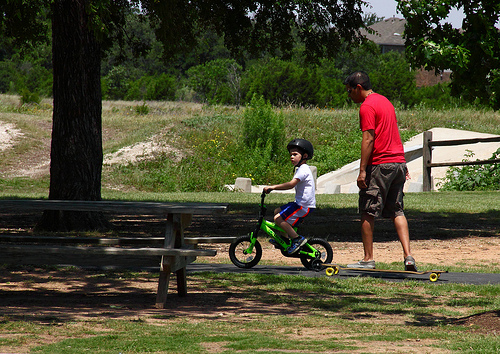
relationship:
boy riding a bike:
[261, 136, 311, 256] [220, 174, 341, 276]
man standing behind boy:
[344, 70, 416, 273] [261, 137, 323, 256]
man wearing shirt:
[344, 70, 416, 273] [346, 88, 431, 166]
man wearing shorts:
[344, 70, 416, 273] [358, 162, 407, 220]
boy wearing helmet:
[261, 136, 318, 252] [284, 137, 319, 157]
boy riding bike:
[261, 136, 318, 252] [230, 181, 335, 275]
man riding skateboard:
[344, 70, 416, 273] [332, 259, 455, 280]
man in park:
[344, 70, 416, 273] [2, 91, 499, 352]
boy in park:
[261, 136, 318, 252] [2, 91, 499, 352]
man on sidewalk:
[344, 70, 416, 273] [99, 258, 499, 286]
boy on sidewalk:
[261, 136, 318, 252] [99, 258, 499, 286]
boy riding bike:
[261, 136, 318, 252] [230, 186, 332, 268]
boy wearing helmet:
[261, 136, 318, 252] [269, 128, 322, 183]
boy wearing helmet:
[261, 136, 318, 252] [285, 136, 315, 160]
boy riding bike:
[261, 136, 318, 252] [225, 185, 342, 279]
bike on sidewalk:
[202, 133, 349, 278] [145, 257, 499, 291]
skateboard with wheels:
[322, 261, 449, 286] [427, 271, 440, 283]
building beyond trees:
[361, 10, 420, 64] [43, 2, 498, 225]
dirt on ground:
[442, 236, 472, 260] [280, 273, 438, 345]